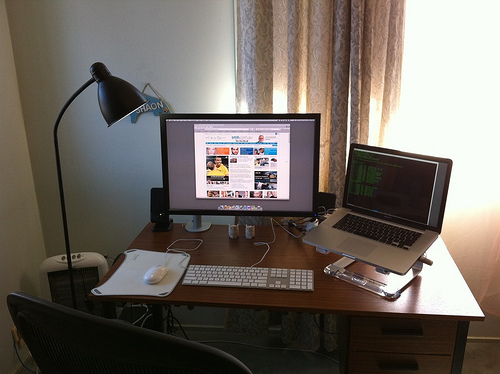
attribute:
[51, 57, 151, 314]
lamp — black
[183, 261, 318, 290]
keyboard — very thin, modern-style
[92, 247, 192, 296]
mouse pad — large, white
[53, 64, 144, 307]
lamp — black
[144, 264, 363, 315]
keyboard — white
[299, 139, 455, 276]
laptop — on, open, black, silver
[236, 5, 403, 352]
curtain — long, neutral-colored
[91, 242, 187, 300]
mousepad — white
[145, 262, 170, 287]
mouse — white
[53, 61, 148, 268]
lamp — black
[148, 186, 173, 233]
speaker — black, small